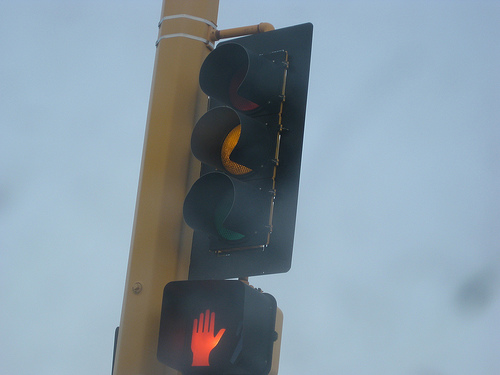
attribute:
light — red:
[220, 64, 274, 114]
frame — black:
[179, 18, 316, 280]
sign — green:
[184, 25, 321, 310]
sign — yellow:
[208, 105, 265, 172]